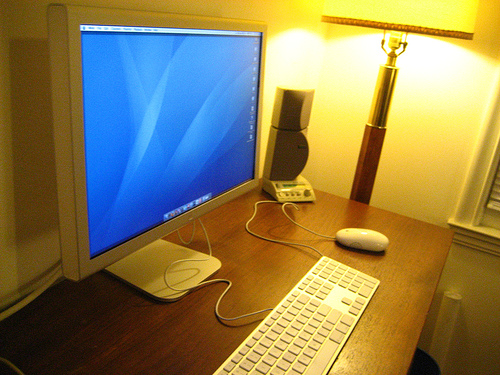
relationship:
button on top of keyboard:
[329, 328, 346, 345] [209, 253, 383, 374]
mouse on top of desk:
[334, 226, 393, 257] [2, 178, 460, 374]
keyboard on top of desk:
[209, 253, 383, 374] [2, 178, 460, 374]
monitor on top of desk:
[44, 3, 273, 285] [2, 178, 460, 374]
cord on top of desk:
[244, 195, 325, 259] [2, 178, 460, 374]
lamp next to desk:
[317, 1, 481, 208] [2, 178, 460, 374]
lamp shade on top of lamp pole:
[316, 1, 483, 44] [346, 29, 410, 206]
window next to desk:
[444, 77, 499, 264] [2, 178, 460, 374]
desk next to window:
[2, 178, 460, 374] [444, 77, 499, 264]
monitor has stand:
[44, 3, 273, 285] [104, 236, 224, 301]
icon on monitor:
[246, 130, 256, 145] [44, 3, 273, 285]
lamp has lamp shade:
[317, 1, 481, 208] [316, 1, 483, 44]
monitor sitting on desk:
[44, 3, 273, 285] [2, 178, 460, 374]